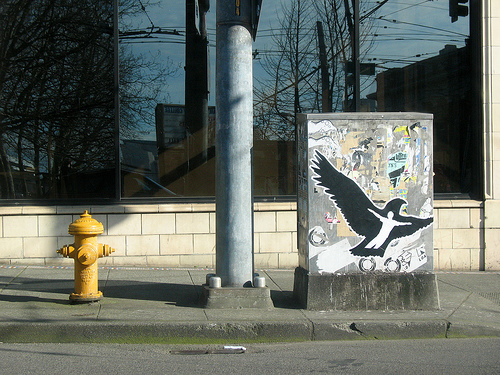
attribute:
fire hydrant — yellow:
[54, 206, 116, 304]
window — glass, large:
[4, 13, 487, 198]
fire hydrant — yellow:
[52, 204, 118, 311]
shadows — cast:
[118, 272, 174, 309]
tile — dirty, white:
[140, 212, 177, 234]